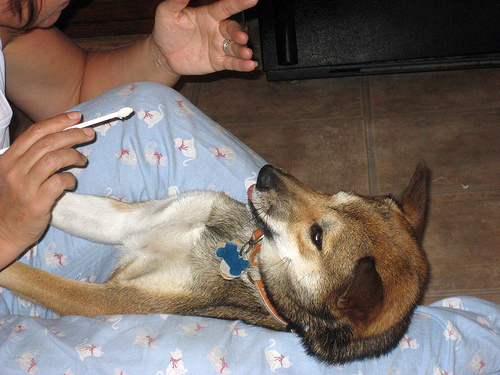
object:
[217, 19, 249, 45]
finger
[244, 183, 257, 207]
tip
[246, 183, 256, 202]
dog's tongue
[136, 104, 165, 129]
cats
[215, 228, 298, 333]
collar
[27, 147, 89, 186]
fingers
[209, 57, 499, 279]
patterns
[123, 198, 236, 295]
chest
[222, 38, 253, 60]
finger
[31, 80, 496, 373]
lap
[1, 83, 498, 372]
pants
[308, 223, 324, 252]
eye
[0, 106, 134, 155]
swab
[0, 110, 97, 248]
right hand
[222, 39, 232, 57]
ring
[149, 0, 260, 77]
hand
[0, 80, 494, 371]
pajamas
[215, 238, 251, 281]
tags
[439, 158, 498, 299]
floor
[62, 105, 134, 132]
ear bud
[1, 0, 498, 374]
person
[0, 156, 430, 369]
dog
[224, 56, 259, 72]
finger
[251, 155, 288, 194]
nose